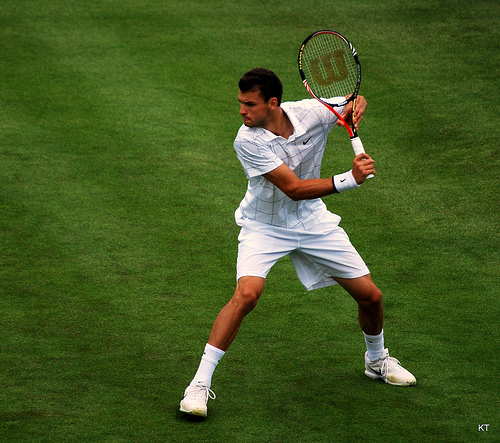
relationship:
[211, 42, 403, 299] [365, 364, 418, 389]
man wearing shoes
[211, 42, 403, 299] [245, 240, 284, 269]
man wearing shorts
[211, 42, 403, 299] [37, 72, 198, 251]
man on court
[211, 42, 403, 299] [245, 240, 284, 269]
man in shorts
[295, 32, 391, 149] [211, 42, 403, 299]
racket on man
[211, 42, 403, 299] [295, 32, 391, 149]
man holding racket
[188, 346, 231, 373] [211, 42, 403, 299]
socks on man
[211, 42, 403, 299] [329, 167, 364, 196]
man wearing wrist band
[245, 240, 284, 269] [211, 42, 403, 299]
shorts on man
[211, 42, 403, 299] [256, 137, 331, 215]
man wearing shirt